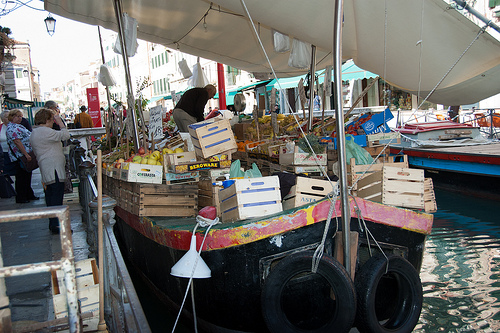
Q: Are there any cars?
A: No, there are no cars.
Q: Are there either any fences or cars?
A: No, there are no cars or fences.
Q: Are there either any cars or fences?
A: No, there are no cars or fences.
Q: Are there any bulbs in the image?
A: No, there are no bulbs.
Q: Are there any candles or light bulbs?
A: No, there are no light bulbs or candles.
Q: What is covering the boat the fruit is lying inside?
A: The canopy is covering the boat.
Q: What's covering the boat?
A: The canopy is covering the boat.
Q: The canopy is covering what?
A: The canopy is covering the boat.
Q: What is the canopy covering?
A: The canopy is covering the boat.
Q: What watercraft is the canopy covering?
A: The canopy is covering the boat.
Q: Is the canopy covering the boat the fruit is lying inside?
A: Yes, the canopy is covering the boat.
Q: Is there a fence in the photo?
A: No, there are no fences.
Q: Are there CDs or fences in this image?
A: No, there are no fences or cds.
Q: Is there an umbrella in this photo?
A: No, there are no umbrellas.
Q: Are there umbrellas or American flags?
A: No, there are no umbrellas or American flags.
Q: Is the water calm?
A: Yes, the water is calm.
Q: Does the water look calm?
A: Yes, the water is calm.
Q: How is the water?
A: The water is calm.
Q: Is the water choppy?
A: No, the water is calm.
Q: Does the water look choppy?
A: No, the water is calm.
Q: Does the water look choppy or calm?
A: The water is calm.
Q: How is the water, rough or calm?
A: The water is calm.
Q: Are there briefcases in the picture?
A: No, there are no briefcases.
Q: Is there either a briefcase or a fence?
A: No, there are no briefcases or fences.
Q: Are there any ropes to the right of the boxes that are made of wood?
A: Yes, there is a rope to the right of the boxes.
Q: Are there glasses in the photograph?
A: No, there are no glasses.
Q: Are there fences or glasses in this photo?
A: No, there are no glasses or fences.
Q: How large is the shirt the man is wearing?
A: The shirt is large.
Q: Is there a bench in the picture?
A: No, there are no benches.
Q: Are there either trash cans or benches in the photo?
A: No, there are no benches or trash cans.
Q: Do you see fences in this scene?
A: No, there are no fences.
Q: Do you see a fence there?
A: No, there are no fences.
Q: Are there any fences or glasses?
A: No, there are no fences or glasses.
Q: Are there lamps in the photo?
A: Yes, there is a lamp.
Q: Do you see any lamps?
A: Yes, there is a lamp.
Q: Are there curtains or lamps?
A: Yes, there is a lamp.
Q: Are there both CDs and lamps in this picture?
A: No, there is a lamp but no cds.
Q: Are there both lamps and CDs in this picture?
A: No, there is a lamp but no cds.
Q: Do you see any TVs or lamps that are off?
A: Yes, the lamp is off.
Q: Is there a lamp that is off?
A: Yes, there is a lamp that is off.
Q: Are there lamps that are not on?
A: Yes, there is a lamp that is off.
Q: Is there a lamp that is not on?
A: Yes, there is a lamp that is off.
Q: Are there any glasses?
A: No, there are no glasses.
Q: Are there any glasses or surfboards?
A: No, there are no glasses or surfboards.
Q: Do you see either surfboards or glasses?
A: No, there are no glasses or surfboards.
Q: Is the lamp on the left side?
A: Yes, the lamp is on the left of the image.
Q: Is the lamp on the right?
A: No, the lamp is on the left of the image.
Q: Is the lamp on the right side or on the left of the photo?
A: The lamp is on the left of the image.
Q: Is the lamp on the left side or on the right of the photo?
A: The lamp is on the left of the image.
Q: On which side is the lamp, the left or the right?
A: The lamp is on the left of the image.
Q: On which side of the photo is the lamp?
A: The lamp is on the left of the image.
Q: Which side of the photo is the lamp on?
A: The lamp is on the left of the image.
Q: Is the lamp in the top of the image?
A: Yes, the lamp is in the top of the image.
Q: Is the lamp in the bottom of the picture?
A: No, the lamp is in the top of the image.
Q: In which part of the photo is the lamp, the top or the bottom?
A: The lamp is in the top of the image.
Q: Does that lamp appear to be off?
A: Yes, the lamp is off.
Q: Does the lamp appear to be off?
A: Yes, the lamp is off.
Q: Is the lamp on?
A: No, the lamp is off.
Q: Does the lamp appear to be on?
A: No, the lamp is off.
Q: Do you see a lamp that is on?
A: No, there is a lamp but it is off.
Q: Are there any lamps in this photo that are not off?
A: No, there is a lamp but it is off.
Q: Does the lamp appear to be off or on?
A: The lamp is off.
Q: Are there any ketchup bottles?
A: No, there are no ketchup bottles.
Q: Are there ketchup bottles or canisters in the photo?
A: No, there are no ketchup bottles or canisters.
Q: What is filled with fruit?
A: The box is filled with fruit.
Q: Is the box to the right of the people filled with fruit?
A: Yes, the box is filled with fruit.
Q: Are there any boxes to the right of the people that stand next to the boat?
A: Yes, there is a box to the right of the people.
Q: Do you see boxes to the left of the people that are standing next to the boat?
A: No, the box is to the right of the people.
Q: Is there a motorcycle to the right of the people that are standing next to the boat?
A: No, there is a box to the right of the people.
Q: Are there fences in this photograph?
A: No, there are no fences.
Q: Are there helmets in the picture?
A: No, there are no helmets.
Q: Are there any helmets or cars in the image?
A: No, there are no helmets or cars.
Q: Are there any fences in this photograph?
A: No, there are no fences.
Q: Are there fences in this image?
A: No, there are no fences.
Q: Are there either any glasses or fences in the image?
A: No, there are no fences or glasses.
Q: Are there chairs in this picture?
A: No, there are no chairs.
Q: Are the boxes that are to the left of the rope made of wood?
A: Yes, the boxes are made of wood.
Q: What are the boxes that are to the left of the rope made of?
A: The boxes are made of wood.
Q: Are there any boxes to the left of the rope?
A: Yes, there are boxes to the left of the rope.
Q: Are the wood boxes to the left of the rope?
A: Yes, the boxes are to the left of the rope.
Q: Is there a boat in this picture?
A: Yes, there is a boat.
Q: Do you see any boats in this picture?
A: Yes, there is a boat.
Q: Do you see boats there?
A: Yes, there is a boat.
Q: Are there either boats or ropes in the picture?
A: Yes, there is a boat.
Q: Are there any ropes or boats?
A: Yes, there is a boat.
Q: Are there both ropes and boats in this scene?
A: Yes, there are both a boat and a rope.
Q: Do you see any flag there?
A: No, there are no flags.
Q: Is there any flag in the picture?
A: No, there are no flags.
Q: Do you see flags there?
A: No, there are no flags.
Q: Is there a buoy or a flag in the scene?
A: No, there are no flags or buoys.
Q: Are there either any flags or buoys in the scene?
A: No, there are no flags or buoys.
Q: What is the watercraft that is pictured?
A: The watercraft is a boat.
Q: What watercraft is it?
A: The watercraft is a boat.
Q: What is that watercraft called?
A: This is a boat.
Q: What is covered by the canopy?
A: The boat is covered by the canopy.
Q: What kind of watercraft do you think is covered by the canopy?
A: The watercraft is a boat.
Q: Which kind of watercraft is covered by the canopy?
A: The watercraft is a boat.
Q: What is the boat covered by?
A: The boat is covered by the canopy.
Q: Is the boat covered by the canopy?
A: Yes, the boat is covered by the canopy.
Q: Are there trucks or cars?
A: No, there are no cars or trucks.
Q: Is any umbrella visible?
A: No, there are no umbrellas.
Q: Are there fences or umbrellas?
A: No, there are no umbrellas or fences.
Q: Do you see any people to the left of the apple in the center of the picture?
A: Yes, there are people to the left of the apple.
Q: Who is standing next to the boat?
A: The people are standing next to the boat.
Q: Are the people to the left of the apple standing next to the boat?
A: Yes, the people are standing next to the boat.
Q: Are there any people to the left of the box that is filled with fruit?
A: Yes, there are people to the left of the box.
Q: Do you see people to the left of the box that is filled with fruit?
A: Yes, there are people to the left of the box.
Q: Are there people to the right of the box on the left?
A: No, the people are to the left of the box.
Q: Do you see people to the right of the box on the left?
A: No, the people are to the left of the box.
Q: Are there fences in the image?
A: No, there are no fences.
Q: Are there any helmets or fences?
A: No, there are no fences or helmets.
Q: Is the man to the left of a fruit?
A: Yes, the man is to the left of a fruit.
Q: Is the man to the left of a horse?
A: No, the man is to the left of a fruit.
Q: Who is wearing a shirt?
A: The man is wearing a shirt.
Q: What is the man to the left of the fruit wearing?
A: The man is wearing a shirt.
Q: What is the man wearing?
A: The man is wearing a shirt.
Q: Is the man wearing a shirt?
A: Yes, the man is wearing a shirt.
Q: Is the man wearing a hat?
A: No, the man is wearing a shirt.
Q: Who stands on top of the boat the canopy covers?
A: The man stands on top of the boat.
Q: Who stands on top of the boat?
A: The man stands on top of the boat.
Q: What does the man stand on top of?
A: The man stands on top of the boat.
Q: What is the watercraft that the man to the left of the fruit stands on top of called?
A: The watercraft is a boat.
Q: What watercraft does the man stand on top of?
A: The man stands on top of the boat.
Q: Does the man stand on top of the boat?
A: Yes, the man stands on top of the boat.